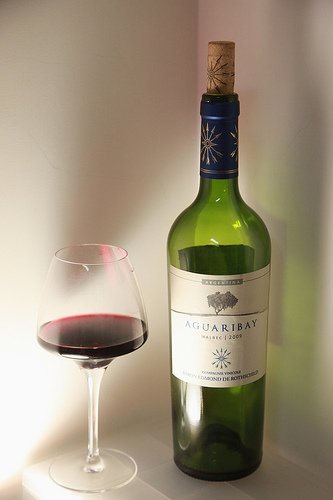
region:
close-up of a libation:
[21, 16, 311, 495]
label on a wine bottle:
[168, 263, 266, 382]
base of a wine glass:
[42, 441, 141, 490]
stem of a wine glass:
[72, 363, 110, 461]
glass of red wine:
[31, 240, 146, 485]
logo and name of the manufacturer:
[178, 285, 261, 329]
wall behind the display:
[10, 183, 157, 233]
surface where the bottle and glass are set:
[147, 480, 310, 495]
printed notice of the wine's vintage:
[197, 330, 240, 338]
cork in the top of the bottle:
[190, 30, 242, 117]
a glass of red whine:
[34, 243, 151, 490]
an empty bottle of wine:
[165, 37, 268, 480]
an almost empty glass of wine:
[34, 242, 147, 492]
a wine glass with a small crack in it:
[30, 242, 147, 488]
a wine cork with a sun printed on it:
[204, 40, 233, 93]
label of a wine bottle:
[167, 261, 267, 387]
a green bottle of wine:
[165, 39, 271, 479]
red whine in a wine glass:
[36, 242, 146, 488]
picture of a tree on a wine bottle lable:
[205, 290, 237, 315]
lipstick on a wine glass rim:
[96, 240, 126, 260]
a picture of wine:
[35, 180, 292, 442]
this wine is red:
[27, 248, 163, 451]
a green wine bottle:
[164, 158, 293, 348]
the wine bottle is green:
[163, 245, 287, 451]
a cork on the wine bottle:
[193, 33, 257, 181]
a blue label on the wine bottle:
[194, 98, 248, 185]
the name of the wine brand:
[182, 316, 261, 346]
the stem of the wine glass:
[42, 368, 136, 460]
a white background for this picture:
[32, 97, 188, 201]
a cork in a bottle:
[194, 39, 236, 91]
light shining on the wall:
[6, 318, 62, 451]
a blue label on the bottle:
[201, 102, 235, 174]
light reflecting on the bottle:
[181, 385, 212, 422]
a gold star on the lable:
[198, 124, 222, 164]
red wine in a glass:
[38, 321, 147, 354]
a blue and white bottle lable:
[168, 262, 265, 390]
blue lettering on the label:
[184, 315, 263, 332]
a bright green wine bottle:
[152, 184, 279, 491]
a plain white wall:
[275, 131, 331, 461]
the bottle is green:
[137, 29, 278, 479]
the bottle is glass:
[153, 35, 289, 495]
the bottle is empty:
[146, 13, 305, 490]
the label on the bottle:
[164, 264, 285, 391]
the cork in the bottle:
[196, 36, 244, 96]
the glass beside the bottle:
[19, 231, 169, 493]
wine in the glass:
[46, 320, 115, 355]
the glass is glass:
[38, 236, 161, 493]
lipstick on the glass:
[88, 244, 113, 258]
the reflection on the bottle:
[227, 215, 240, 234]